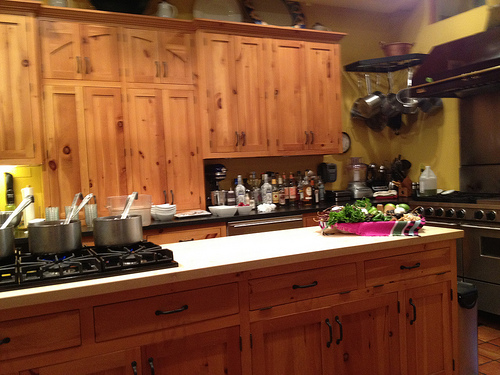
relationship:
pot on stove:
[24, 217, 84, 254] [0, 238, 177, 290]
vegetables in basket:
[320, 198, 410, 221] [328, 218, 425, 232]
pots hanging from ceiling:
[349, 87, 437, 127] [345, 40, 437, 76]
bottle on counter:
[236, 173, 248, 208] [210, 191, 395, 218]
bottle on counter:
[258, 170, 271, 207] [210, 191, 395, 218]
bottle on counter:
[270, 176, 278, 206] [210, 191, 395, 218]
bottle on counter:
[299, 170, 313, 202] [210, 191, 395, 218]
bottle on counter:
[286, 169, 296, 200] [210, 191, 395, 218]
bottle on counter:
[280, 172, 290, 206] [210, 191, 395, 218]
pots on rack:
[349, 87, 436, 135] [342, 40, 435, 87]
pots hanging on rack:
[349, 87, 436, 135] [343, 36, 435, 83]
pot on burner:
[24, 218, 85, 254] [21, 180, 173, 276]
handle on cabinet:
[154, 300, 189, 318] [113, 246, 425, 353]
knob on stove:
[455, 206, 466, 219] [396, 185, 497, 321]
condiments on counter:
[226, 172, 306, 201] [202, 186, 331, 259]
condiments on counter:
[227, 172, 326, 205] [222, 204, 312, 230]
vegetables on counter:
[320, 197, 422, 229] [297, 228, 427, 276]